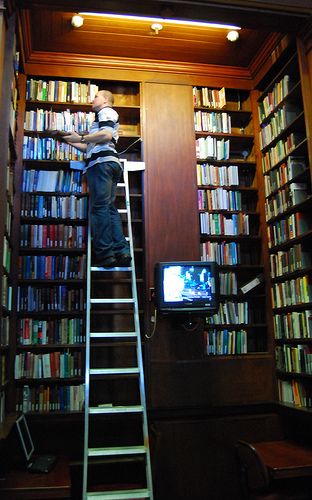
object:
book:
[1, 317, 9, 347]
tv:
[151, 260, 223, 318]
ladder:
[80, 156, 155, 498]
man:
[61, 89, 133, 269]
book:
[64, 283, 86, 307]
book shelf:
[21, 73, 144, 105]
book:
[216, 85, 230, 109]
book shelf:
[186, 81, 253, 112]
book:
[204, 332, 216, 355]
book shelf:
[195, 185, 264, 214]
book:
[227, 329, 245, 353]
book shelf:
[198, 236, 267, 270]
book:
[239, 270, 261, 294]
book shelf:
[215, 267, 268, 301]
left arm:
[75, 109, 113, 144]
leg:
[86, 163, 116, 268]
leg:
[110, 159, 136, 267]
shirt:
[79, 106, 124, 174]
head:
[87, 90, 117, 109]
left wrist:
[77, 132, 89, 147]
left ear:
[104, 95, 109, 102]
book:
[50, 382, 66, 411]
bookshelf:
[8, 347, 90, 385]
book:
[218, 237, 243, 263]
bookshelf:
[193, 161, 258, 191]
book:
[201, 213, 212, 232]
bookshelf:
[189, 134, 258, 159]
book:
[201, 241, 214, 262]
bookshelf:
[189, 110, 259, 139]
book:
[42, 253, 59, 277]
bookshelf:
[16, 218, 148, 255]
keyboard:
[25, 449, 59, 475]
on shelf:
[21, 99, 146, 138]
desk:
[238, 430, 311, 499]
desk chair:
[230, 435, 271, 498]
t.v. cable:
[139, 306, 160, 342]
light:
[70, 12, 84, 29]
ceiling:
[0, 2, 301, 66]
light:
[149, 22, 164, 34]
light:
[225, 29, 240, 41]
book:
[71, 255, 86, 278]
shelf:
[266, 198, 311, 244]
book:
[231, 191, 241, 211]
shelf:
[273, 301, 311, 338]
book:
[40, 386, 54, 418]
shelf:
[265, 174, 311, 223]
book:
[278, 378, 287, 401]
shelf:
[271, 275, 311, 315]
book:
[16, 353, 26, 376]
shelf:
[258, 47, 300, 128]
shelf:
[268, 247, 311, 278]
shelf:
[262, 136, 308, 199]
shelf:
[274, 340, 312, 379]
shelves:
[186, 47, 311, 417]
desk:
[2, 423, 71, 489]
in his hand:
[57, 123, 87, 144]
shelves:
[4, 1, 311, 500]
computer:
[13, 413, 58, 473]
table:
[2, 98, 76, 496]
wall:
[142, 77, 225, 431]